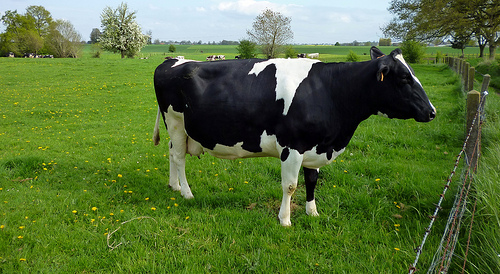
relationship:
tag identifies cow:
[376, 72, 384, 80] [154, 45, 437, 227]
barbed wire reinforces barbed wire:
[409, 102, 481, 272] [409, 52, 491, 274]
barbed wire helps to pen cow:
[409, 52, 491, 274] [154, 45, 437, 227]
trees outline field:
[2, 5, 82, 57] [14, 54, 275, 230]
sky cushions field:
[0, 0, 393, 44] [0, 45, 498, 274]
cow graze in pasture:
[154, 45, 437, 227] [5, 230, 498, 270]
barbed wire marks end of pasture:
[409, 52, 491, 274] [2, 42, 497, 272]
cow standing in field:
[154, 45, 437, 227] [0, 45, 498, 274]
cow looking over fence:
[180, 57, 417, 209] [427, 27, 484, 245]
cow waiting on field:
[154, 45, 437, 227] [0, 45, 498, 274]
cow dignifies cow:
[154, 45, 437, 227] [154, 45, 437, 227]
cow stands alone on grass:
[154, 45, 437, 227] [17, 157, 337, 256]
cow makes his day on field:
[154, 45, 437, 227] [15, 38, 419, 258]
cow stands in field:
[154, 45, 437, 227] [0, 33, 429, 251]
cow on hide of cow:
[154, 45, 437, 227] [154, 45, 437, 227]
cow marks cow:
[154, 45, 437, 227] [154, 45, 437, 227]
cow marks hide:
[154, 45, 437, 227] [159, 63, 335, 147]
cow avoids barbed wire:
[154, 45, 437, 227] [409, 52, 491, 274]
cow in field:
[154, 45, 437, 227] [0, 43, 499, 272]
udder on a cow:
[173, 126, 210, 162] [154, 45, 437, 227]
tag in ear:
[380, 73, 384, 82] [376, 55, 388, 88]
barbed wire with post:
[409, 52, 491, 274] [466, 90, 480, 172]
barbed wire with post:
[409, 52, 491, 274] [480, 73, 490, 117]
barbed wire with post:
[409, 52, 491, 274] [467, 64, 474, 90]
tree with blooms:
[95, 5, 160, 69] [132, 20, 136, 26]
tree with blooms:
[95, 5, 160, 69] [135, 34, 142, 41]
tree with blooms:
[95, 5, 160, 69] [104, 38, 113, 47]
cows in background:
[206, 53, 225, 62] [0, 35, 499, 72]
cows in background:
[297, 53, 307, 59] [0, 35, 499, 72]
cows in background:
[304, 51, 322, 60] [0, 35, 499, 72]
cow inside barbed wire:
[154, 45, 437, 227] [409, 52, 491, 274]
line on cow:
[397, 50, 441, 113] [154, 45, 437, 227]